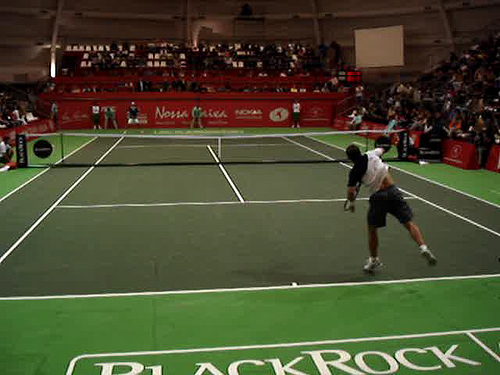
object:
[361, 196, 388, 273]
legs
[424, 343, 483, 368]
letter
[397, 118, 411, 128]
racket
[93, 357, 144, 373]
letter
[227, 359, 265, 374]
white letter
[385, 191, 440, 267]
leg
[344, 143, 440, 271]
tennis player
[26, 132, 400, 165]
net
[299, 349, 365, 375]
letter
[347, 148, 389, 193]
t-shirt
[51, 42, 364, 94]
spectators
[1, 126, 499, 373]
ground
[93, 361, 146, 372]
letter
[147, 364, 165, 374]
letter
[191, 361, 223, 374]
letter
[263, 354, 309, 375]
letter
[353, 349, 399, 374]
letter